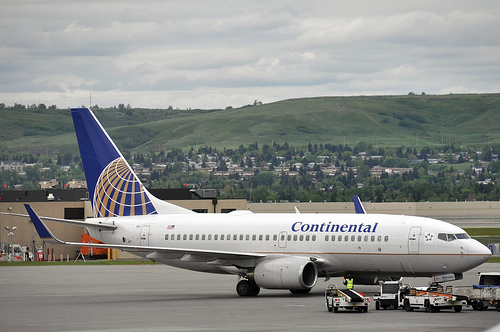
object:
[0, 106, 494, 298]
plane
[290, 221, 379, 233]
logo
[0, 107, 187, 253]
tail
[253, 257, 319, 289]
engine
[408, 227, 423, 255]
door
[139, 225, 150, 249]
back door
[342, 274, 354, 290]
crew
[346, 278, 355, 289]
yellow vest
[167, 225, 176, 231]
flag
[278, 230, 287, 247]
middle door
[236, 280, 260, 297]
tires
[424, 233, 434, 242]
star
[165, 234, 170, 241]
window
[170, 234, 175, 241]
window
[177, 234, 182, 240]
window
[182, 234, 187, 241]
window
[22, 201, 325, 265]
wing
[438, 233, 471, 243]
windshield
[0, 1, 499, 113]
sky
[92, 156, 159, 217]
graphic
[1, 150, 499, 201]
town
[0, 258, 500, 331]
tarmac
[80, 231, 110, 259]
tug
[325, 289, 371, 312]
vehicles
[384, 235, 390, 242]
windows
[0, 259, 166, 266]
grass